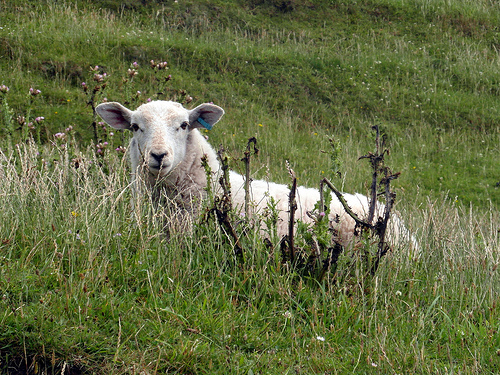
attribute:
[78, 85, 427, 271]
sheep — adult, white, tan, looking forward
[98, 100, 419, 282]
sheep — adult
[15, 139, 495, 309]
tall weeds — dark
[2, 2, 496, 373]
grass — bunch, wild, sprouted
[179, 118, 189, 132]
black eye — dark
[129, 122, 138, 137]
black eye — dark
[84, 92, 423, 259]
sheep — adult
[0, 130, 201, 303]
grass — white, tall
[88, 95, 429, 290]
sheep — brown, white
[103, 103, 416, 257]
sheep — adult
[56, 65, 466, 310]
sheep — adult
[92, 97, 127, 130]
ear — white, long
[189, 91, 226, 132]
ear — white, long